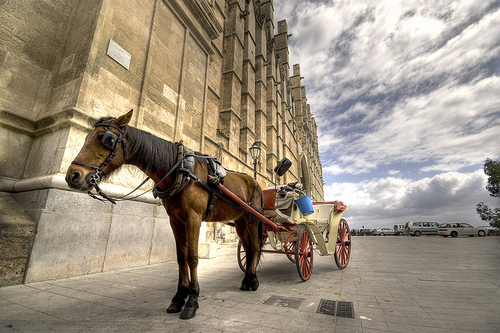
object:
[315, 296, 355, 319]
grate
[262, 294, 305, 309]
grate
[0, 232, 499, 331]
ground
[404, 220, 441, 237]
car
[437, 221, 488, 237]
car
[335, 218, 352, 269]
spokes wheel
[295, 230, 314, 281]
spokes wheel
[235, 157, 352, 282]
carriage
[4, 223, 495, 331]
stone road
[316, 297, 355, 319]
drainage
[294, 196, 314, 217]
bucket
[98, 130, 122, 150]
block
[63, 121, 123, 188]
face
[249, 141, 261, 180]
lamp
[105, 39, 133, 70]
plaque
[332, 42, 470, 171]
clouds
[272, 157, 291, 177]
mirror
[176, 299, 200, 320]
hooves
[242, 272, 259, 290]
hooves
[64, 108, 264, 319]
horse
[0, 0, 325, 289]
building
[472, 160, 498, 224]
tree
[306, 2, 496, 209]
sky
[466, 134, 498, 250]
side